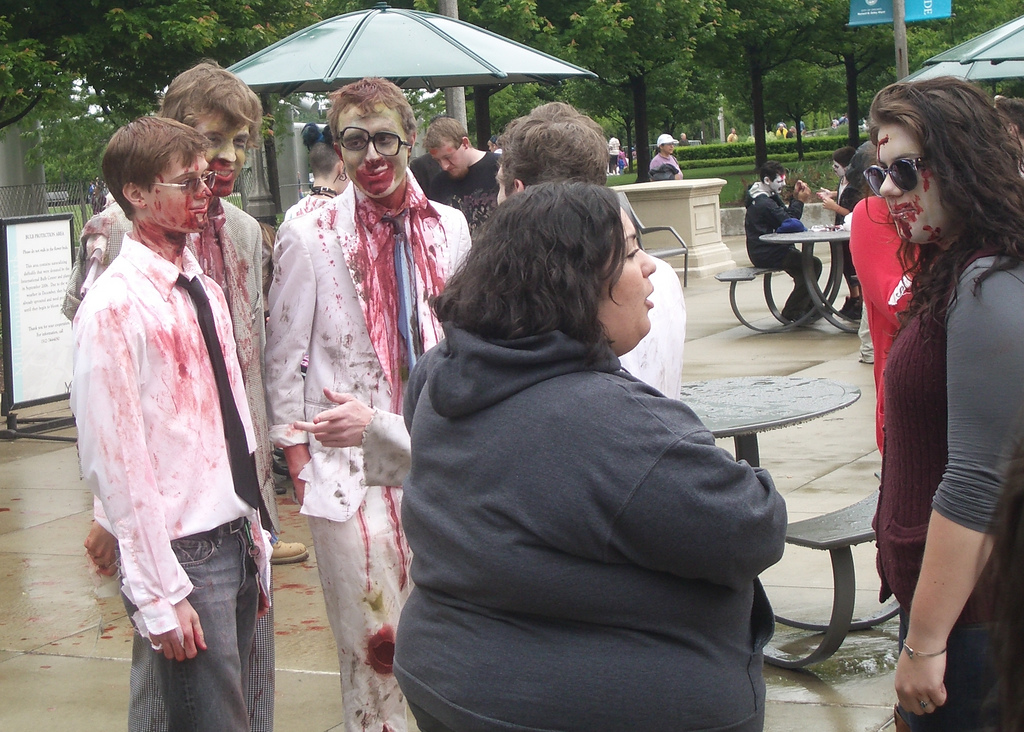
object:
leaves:
[692, 27, 771, 170]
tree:
[692, 27, 771, 170]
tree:
[591, 8, 678, 198]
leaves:
[150, 3, 238, 76]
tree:
[150, 3, 238, 76]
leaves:
[591, 8, 775, 158]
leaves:
[539, 25, 645, 123]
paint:
[288, 97, 479, 266]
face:
[288, 97, 479, 266]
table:
[714, 387, 936, 651]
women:
[410, 179, 936, 650]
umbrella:
[262, 27, 508, 93]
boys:
[163, 46, 264, 319]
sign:
[17, 223, 100, 421]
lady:
[417, 203, 708, 653]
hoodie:
[417, 203, 708, 653]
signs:
[844, 6, 892, 27]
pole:
[844, 47, 964, 99]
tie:
[151, 258, 275, 485]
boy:
[262, 83, 404, 670]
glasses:
[341, 120, 408, 152]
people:
[657, 106, 807, 161]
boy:
[72, 139, 289, 726]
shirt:
[72, 139, 258, 644]